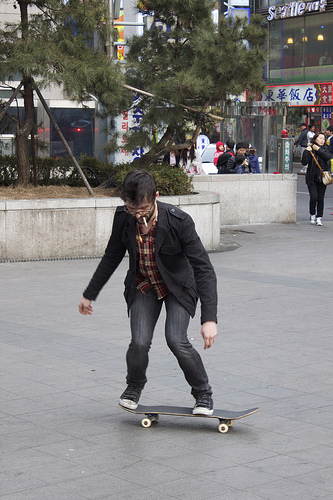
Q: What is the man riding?
A: Skateboard.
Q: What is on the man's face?
A: Glasses.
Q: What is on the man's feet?
A: Sneakers.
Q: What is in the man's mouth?
A: Cigarette.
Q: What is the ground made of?
A: Concrete.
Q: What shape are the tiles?
A: Square.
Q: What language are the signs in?
A: Chinese.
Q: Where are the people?
A: On the sidewalk.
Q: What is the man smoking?
A: Cigarette.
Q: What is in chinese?
A: The signs.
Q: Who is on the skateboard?
A: A man.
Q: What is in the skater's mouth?
A: Cigarette.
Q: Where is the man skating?
A: On the sidewalk.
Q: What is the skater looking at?
A: The ground.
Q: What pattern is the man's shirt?
A: Plaid.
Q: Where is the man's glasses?
A: On his face.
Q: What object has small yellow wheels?
A: The skateboard.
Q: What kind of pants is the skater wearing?
A: Grey jeans.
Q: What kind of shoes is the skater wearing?
A: Black and white skate shoes.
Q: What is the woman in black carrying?
A: Brown and white bag.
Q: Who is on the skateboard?
A: The man.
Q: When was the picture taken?
A: Daytime.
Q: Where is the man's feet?
A: On the skateboard.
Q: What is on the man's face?
A: Glasses.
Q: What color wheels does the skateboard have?
A: White.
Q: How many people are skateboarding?
A: One.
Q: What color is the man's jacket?
A: Black.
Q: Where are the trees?
A: In the landscaping.